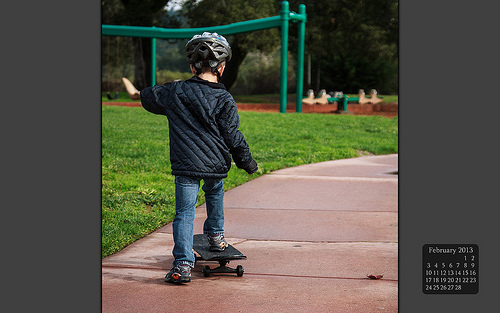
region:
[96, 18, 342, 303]
a little boy on a skateboard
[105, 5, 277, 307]
a little boy skateboarding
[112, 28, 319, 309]
he is trying to skateboard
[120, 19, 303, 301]
he is skateboarding in a park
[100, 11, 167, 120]
this is a swingset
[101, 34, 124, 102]
this is a swing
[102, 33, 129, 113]
the swing is black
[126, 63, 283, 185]
this is a black jacket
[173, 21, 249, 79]
this is a helmet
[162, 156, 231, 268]
this is a pair of blue jeans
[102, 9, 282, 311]
a little bow riding a skateboard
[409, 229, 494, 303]
this is a calendar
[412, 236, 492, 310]
a very small calendar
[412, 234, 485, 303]
a February 2013 calendar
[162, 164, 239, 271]
he is wearing blue jeans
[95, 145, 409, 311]
the walkway is wet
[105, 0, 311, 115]
a green jungle gym playground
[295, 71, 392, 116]
this is a teeter totter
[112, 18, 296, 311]
he is wearing a helmet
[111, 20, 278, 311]
a small child on a skateboard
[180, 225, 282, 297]
a black skateboard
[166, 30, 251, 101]
a child wearing a helmet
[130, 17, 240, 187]
a child wearing a jacket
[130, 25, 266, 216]
a child wearing a black jacket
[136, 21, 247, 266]
a child wearing jeans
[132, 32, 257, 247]
a child wearing blue jeans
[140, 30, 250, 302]
a child wearing sneakers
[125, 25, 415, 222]
a child outdoors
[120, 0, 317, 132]
green monkey bars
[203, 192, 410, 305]
the sidewalk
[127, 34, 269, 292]
a kid on a skateboard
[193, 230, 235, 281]
the skateboard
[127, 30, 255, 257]
a kid in a black coat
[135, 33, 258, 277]
a kid with a helmet on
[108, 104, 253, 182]
grass next to the sidewalk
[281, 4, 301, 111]
green posts in the grass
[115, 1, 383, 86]
trees behind the playground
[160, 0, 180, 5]
the sky through the trees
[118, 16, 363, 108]
a playground